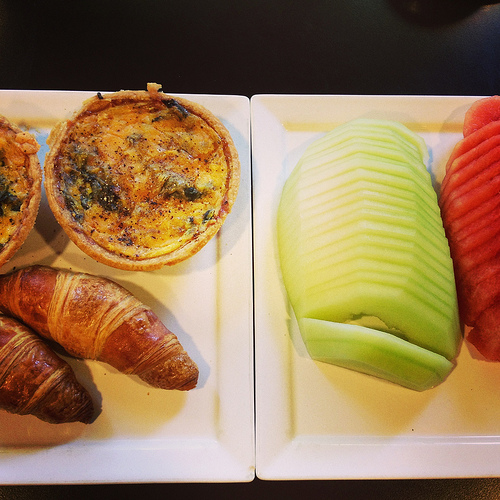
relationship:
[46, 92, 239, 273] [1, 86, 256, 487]
quiche on a plate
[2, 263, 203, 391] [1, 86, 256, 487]
croissant on plate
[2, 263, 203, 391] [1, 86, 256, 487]
croissant on a plate